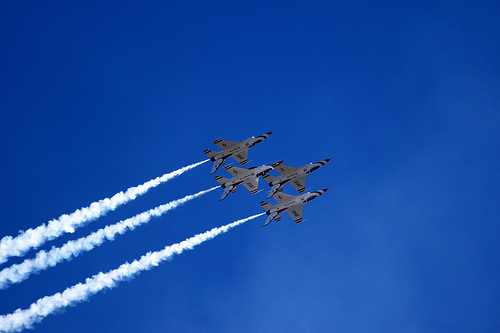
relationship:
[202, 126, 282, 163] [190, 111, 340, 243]
plane in formation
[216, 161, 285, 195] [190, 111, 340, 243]
plane in formation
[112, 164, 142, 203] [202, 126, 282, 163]
smoke behind plane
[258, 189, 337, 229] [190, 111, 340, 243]
plane in formation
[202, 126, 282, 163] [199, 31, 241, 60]
plane in sky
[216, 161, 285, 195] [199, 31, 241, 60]
plane in sky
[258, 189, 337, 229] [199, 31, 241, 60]
plane in sky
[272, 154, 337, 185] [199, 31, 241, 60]
plane in sky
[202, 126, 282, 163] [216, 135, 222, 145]
plane has wing